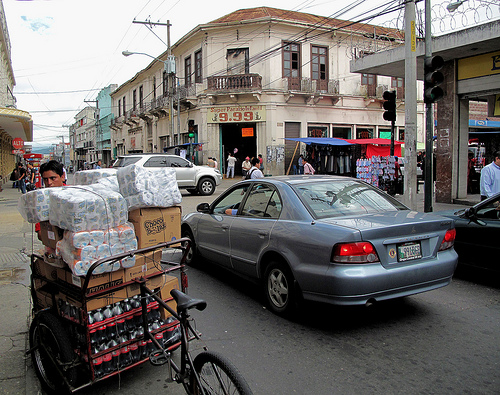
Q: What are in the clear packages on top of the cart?
A: Toilet paper.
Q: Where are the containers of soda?
A: On the bottom of the cart.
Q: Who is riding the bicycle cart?
A: No one is.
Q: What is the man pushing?
A: A cart.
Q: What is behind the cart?
A: A bicycle.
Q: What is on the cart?
A: White packaging.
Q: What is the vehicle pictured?
A: A blue car.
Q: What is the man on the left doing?
A: Pushing supplies down a street.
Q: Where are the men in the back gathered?
A: In front of a store.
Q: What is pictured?
A: A busy city street.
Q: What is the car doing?
A: Stopping.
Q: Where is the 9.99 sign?
A: On the building.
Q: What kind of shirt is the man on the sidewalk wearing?
A: A blue dress shirt.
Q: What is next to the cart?
A: A gray car.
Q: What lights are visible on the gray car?
A: Brake lights.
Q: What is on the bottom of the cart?
A: Soda bottles.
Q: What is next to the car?
A: A cart.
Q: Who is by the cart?
A: A man.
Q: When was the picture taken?
A: During the day.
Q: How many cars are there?
A: Three.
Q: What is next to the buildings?
A: Power lines.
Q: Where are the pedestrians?
A: On the sidewalk.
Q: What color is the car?
A: Blue.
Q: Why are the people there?
A: To go to the stores.